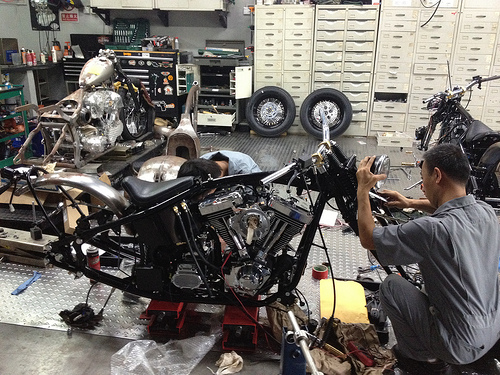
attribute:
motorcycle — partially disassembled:
[74, 85, 386, 338]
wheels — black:
[246, 84, 362, 144]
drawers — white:
[255, 9, 371, 136]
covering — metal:
[2, 138, 439, 344]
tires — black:
[242, 73, 353, 142]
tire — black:
[298, 86, 352, 143]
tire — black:
[246, 84, 294, 135]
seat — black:
[118, 167, 208, 218]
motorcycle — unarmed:
[37, 94, 435, 351]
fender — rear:
[13, 170, 133, 218]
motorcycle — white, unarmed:
[12, 42, 162, 171]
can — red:
[18, 47, 28, 68]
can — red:
[24, 48, 30, 68]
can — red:
[28, 48, 38, 70]